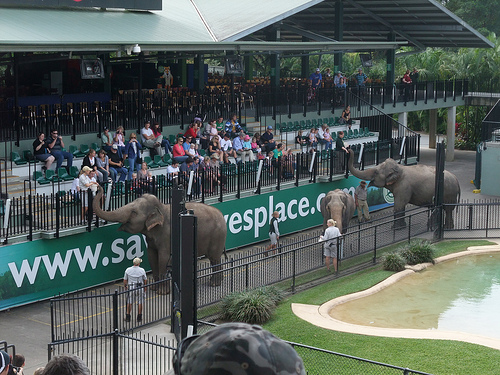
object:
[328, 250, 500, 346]
water